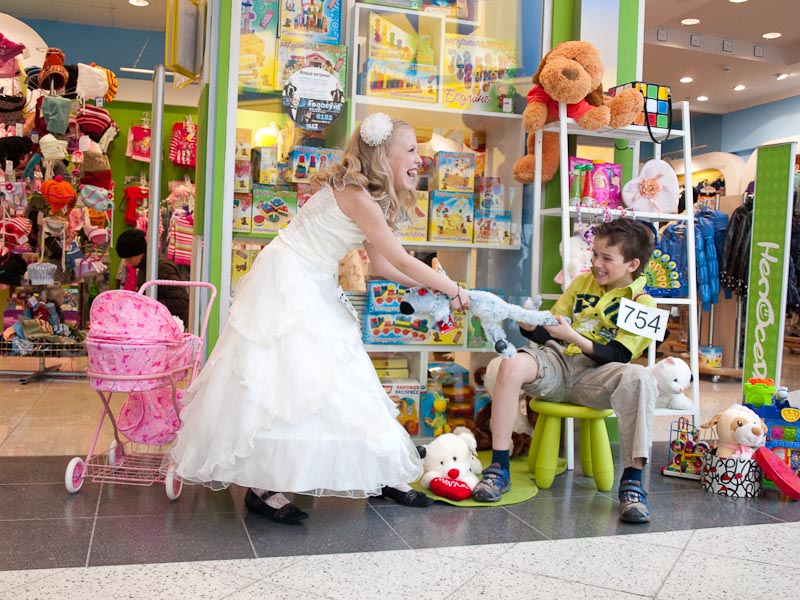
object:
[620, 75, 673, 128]
toy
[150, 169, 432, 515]
young girl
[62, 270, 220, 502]
baby carriage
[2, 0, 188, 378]
clothing store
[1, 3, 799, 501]
baby clothes/toys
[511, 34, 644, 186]
stuffed bear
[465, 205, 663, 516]
kid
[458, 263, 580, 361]
animal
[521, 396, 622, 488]
stool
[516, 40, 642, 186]
dog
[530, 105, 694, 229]
shelf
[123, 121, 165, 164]
shirts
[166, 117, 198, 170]
shirts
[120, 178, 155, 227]
shirts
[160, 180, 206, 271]
shirts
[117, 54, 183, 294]
racks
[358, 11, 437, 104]
toys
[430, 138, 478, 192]
toys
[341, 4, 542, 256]
shelf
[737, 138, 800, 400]
sign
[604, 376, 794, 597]
ground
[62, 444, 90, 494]
wheels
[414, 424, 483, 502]
stuffed animal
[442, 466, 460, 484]
red nose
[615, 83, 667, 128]
rubik cube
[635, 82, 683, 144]
black strap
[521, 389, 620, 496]
green stool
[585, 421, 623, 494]
leg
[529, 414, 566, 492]
leg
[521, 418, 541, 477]
leg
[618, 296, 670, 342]
white card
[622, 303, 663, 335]
number 754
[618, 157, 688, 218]
box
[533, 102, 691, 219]
shelf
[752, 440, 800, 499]
red top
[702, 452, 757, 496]
box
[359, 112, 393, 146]
white bow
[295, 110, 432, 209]
hair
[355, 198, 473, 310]
arm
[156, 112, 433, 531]
girl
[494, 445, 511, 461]
sock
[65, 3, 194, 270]
wall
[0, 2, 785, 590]
building